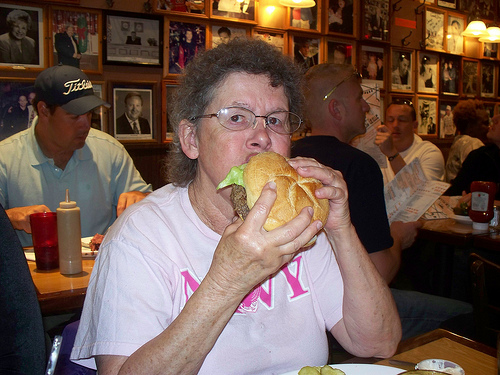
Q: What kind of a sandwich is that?
A: A hamburger.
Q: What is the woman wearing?
A: Glasses.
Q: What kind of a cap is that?
A: A Titleist hat.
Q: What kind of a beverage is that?
A: Coke.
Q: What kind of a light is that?
A: A hanging light.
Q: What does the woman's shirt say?
A: Navy.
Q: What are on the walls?
A: Photos.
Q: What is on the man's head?
A: Sunglasses.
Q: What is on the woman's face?
A: Glasses.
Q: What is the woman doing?
A: Eating a burger.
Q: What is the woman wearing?
A: A t-shirt.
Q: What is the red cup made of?
A: Plastic.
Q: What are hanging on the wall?
A: Framed photos.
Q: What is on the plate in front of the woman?
A: Pickles.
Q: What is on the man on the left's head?
A: A hat.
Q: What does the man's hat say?
A: Titleist.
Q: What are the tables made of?
A: Wood.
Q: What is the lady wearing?
A: Clothes.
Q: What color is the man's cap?
A: Black.